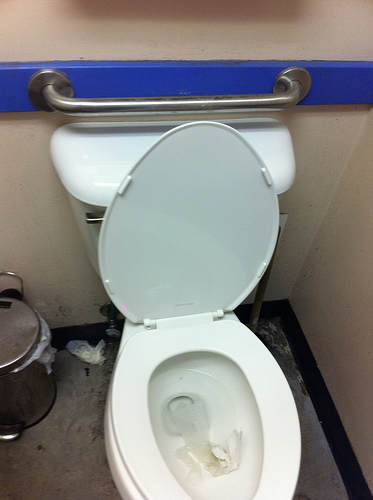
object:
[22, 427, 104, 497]
floor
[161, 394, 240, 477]
tissue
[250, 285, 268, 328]
plunger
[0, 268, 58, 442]
can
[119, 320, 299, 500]
seat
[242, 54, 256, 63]
ground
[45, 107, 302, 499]
toilet bowl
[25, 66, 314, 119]
bar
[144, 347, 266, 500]
bowl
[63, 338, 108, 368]
paper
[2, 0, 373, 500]
bathroom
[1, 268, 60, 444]
trash can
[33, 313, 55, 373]
trash bag